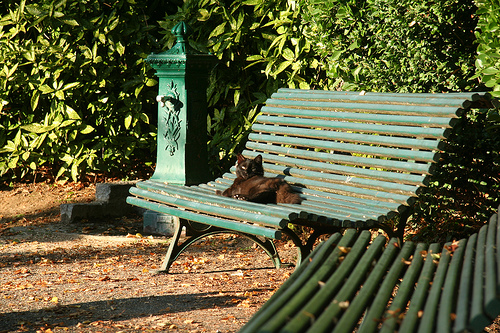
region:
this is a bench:
[134, 59, 474, 239]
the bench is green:
[119, 67, 481, 267]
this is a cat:
[217, 137, 302, 227]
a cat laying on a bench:
[142, 68, 468, 264]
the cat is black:
[216, 142, 320, 227]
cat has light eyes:
[226, 159, 260, 173]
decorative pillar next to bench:
[133, 17, 217, 238]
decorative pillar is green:
[140, 21, 227, 249]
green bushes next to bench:
[2, 0, 482, 177]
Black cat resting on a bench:
[220, 149, 302, 209]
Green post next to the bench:
[145, 21, 219, 232]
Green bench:
[125, 91, 486, 273]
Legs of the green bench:
[155, 216, 322, 273]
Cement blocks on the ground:
[60, 178, 140, 220]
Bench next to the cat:
[242, 211, 497, 331]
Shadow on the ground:
[1, 291, 248, 332]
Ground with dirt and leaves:
[2, 172, 499, 330]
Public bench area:
[0, 0, 497, 330]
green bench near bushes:
[198, 90, 446, 308]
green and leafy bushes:
[225, 10, 497, 181]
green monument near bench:
[119, 34, 216, 257]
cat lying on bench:
[223, 152, 280, 200]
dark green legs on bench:
[153, 206, 281, 281]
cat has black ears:
[223, 149, 270, 159]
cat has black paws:
[235, 183, 262, 199]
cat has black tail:
[248, 181, 295, 206]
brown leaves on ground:
[10, 238, 275, 328]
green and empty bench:
[282, 233, 497, 330]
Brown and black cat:
[217, 150, 303, 206]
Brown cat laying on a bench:
[216, 151, 303, 208]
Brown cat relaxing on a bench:
[212, 146, 302, 207]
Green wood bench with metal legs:
[125, 83, 493, 273]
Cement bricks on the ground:
[56, 175, 147, 222]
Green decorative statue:
[133, 19, 217, 199]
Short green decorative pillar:
[135, 19, 221, 201]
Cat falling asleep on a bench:
[212, 150, 304, 206]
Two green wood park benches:
[124, 85, 496, 331]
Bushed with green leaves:
[0, 1, 497, 206]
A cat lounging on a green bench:
[195, 140, 312, 219]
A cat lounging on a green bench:
[205, 143, 315, 220]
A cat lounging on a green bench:
[207, 148, 312, 210]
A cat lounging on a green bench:
[210, 141, 312, 214]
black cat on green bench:
[221, 130, 302, 215]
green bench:
[299, 219, 486, 325]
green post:
[141, 19, 204, 175]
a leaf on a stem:
[141, 114, 150, 125]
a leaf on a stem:
[65, 158, 79, 175]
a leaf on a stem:
[49, 163, 72, 183]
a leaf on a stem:
[29, 157, 36, 171]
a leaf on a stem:
[18, 151, 30, 160]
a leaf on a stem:
[8, 157, 17, 167]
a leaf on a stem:
[55, 120, 76, 127]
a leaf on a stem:
[30, 125, 47, 135]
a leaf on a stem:
[11, 130, 23, 146]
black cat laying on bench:
[221, 155, 302, 206]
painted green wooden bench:
[138, 95, 473, 227]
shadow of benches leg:
[195, 258, 251, 278]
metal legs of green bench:
[144, 240, 292, 269]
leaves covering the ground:
[26, 264, 119, 294]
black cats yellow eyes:
[241, 164, 255, 171]